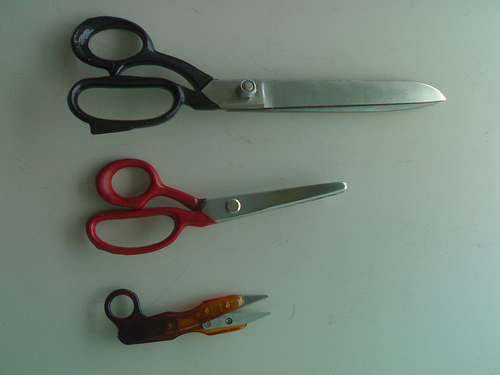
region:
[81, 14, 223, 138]
The scissors have a black handle.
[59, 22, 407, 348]
Three pair of scissors on the table.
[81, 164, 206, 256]
The scissors handle is red.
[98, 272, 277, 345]
A pair of funny looking scissors.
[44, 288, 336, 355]
The scissors are little.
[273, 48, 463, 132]
The blade of the scissors.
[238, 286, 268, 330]
The small blade on the scissors.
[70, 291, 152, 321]
The handle is round.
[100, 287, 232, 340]
The scissors is brown.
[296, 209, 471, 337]
The table is white.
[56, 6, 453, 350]
three pairs of scissors lay on a table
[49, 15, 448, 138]
the largest pair have a black handle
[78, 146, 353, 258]
the pair in the middle have a red handle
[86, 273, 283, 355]
the smallest pair has a dark brown handle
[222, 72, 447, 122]
the scissors blades are silver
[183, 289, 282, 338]
the smallest pair has it's blade ajar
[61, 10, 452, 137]
the largest pair are fabric scissors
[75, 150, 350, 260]
the red handled scissors are common household scissors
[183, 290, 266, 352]
the upper half of the scissors are orange in color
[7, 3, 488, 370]
the scissors lay on a white surface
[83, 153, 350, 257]
medium pair of scissors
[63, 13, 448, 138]
the extra large pair of scissors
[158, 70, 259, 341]
the bolts on scissors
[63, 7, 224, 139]
a black handle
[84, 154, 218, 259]
a red handle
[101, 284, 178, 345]
the brown handle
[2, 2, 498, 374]
the white table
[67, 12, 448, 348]
all the scissors and snippets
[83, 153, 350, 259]
the pair in middle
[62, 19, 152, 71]
the scissors are black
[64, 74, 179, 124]
the scissors is black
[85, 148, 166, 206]
the scissors are red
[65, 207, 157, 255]
the scissors are red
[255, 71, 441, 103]
the scissors are silver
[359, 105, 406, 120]
the scissors are silver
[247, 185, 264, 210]
the scissors are silver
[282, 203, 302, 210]
the scissors are silver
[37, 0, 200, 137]
handle of the scissors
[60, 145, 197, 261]
handle of the scissors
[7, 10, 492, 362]
scissors on a flat white surface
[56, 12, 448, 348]
large scissor over two smaller scissors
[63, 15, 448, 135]
black handle with silver blades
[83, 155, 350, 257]
red handle on silver blades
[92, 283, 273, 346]
single plastic ring on brown-handled clipper with short blades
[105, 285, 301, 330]
curved hair by pointed blades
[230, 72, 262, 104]
raised screw on blade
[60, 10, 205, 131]
round and oval opening on scissor handle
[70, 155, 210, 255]
smaller round hole than oval hole on handle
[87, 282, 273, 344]
seam ripper with opening for thumb